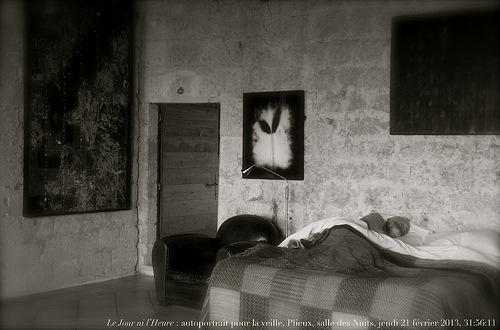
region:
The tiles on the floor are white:
[30, 293, 158, 327]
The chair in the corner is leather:
[148, 212, 288, 309]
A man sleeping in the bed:
[252, 211, 417, 274]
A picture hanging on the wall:
[234, 88, 310, 186]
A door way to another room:
[135, 87, 225, 278]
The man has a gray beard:
[384, 212, 414, 239]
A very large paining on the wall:
[12, 5, 147, 222]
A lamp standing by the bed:
[238, 161, 298, 246]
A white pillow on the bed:
[424, 228, 498, 273]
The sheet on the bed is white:
[273, 207, 496, 281]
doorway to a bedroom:
[138, 86, 229, 271]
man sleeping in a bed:
[342, 198, 421, 250]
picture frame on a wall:
[223, 81, 333, 191]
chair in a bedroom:
[146, 225, 232, 313]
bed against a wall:
[198, 204, 494, 329]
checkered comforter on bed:
[261, 268, 453, 315]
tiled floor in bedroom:
[43, 291, 165, 326]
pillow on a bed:
[432, 218, 498, 263]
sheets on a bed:
[382, 239, 449, 257]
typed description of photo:
[102, 309, 497, 329]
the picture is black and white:
[2, 6, 495, 321]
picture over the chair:
[187, 69, 324, 197]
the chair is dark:
[131, 197, 283, 309]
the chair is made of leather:
[131, 185, 292, 305]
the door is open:
[112, 87, 227, 266]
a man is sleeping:
[274, 195, 426, 305]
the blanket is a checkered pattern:
[206, 235, 435, 317]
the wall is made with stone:
[312, 134, 474, 214]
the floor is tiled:
[42, 285, 165, 321]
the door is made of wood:
[131, 101, 240, 234]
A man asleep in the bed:
[288, 208, 458, 273]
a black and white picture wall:
[243, 87, 318, 189]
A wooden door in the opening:
[149, 94, 244, 253]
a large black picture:
[20, 0, 152, 241]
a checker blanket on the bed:
[252, 213, 454, 295]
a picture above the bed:
[387, 12, 499, 303]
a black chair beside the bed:
[144, 211, 277, 312]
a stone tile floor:
[31, 282, 161, 318]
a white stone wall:
[22, 210, 129, 287]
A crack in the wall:
[123, 210, 147, 278]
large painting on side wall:
[17, 7, 136, 222]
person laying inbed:
[282, 196, 409, 279]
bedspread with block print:
[202, 231, 489, 318]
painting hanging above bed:
[379, 7, 498, 132]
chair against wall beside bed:
[138, 210, 281, 296]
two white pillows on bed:
[382, 213, 498, 245]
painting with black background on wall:
[237, 88, 301, 176]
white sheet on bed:
[285, 215, 477, 270]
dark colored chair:
[152, 210, 276, 304]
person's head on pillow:
[378, 212, 418, 238]